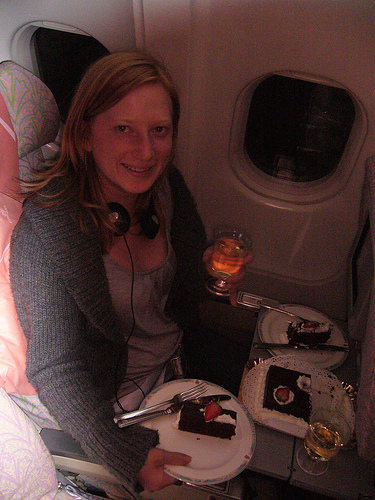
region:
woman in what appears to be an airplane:
[2, 4, 372, 496]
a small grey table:
[238, 296, 360, 491]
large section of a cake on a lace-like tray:
[240, 355, 355, 438]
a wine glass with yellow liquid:
[294, 408, 351, 473]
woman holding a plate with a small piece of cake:
[134, 376, 252, 483]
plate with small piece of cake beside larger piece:
[255, 301, 353, 431]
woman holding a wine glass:
[199, 227, 253, 306]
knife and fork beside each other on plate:
[112, 379, 256, 484]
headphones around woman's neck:
[79, 175, 164, 239]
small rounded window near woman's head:
[76, 49, 367, 195]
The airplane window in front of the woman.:
[246, 61, 352, 197]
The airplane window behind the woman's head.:
[20, 21, 109, 124]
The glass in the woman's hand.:
[214, 227, 242, 307]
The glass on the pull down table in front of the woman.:
[314, 407, 345, 477]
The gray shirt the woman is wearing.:
[71, 189, 173, 373]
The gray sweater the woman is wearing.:
[21, 175, 215, 478]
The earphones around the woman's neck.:
[83, 184, 161, 240]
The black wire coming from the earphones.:
[119, 236, 145, 420]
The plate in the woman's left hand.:
[130, 372, 264, 489]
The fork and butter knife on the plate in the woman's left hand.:
[114, 384, 225, 423]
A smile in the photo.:
[116, 155, 160, 179]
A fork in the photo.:
[115, 379, 210, 419]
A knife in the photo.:
[174, 391, 234, 411]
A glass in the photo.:
[296, 423, 339, 476]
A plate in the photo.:
[199, 443, 255, 483]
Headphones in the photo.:
[106, 203, 168, 238]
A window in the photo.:
[234, 60, 363, 205]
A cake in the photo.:
[176, 404, 241, 439]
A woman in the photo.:
[14, 48, 209, 485]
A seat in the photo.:
[0, 61, 68, 404]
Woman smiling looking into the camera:
[15, 49, 204, 384]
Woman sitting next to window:
[14, 61, 206, 361]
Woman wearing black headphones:
[9, 45, 202, 385]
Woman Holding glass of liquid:
[8, 47, 260, 356]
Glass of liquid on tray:
[291, 403, 355, 480]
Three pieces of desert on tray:
[147, 276, 337, 486]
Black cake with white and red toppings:
[256, 360, 319, 432]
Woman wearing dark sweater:
[14, 71, 216, 382]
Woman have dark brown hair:
[19, 52, 181, 216]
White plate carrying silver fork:
[129, 379, 264, 499]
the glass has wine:
[184, 238, 262, 289]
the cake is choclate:
[163, 392, 248, 437]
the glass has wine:
[299, 411, 358, 468]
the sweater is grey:
[33, 263, 123, 394]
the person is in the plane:
[17, 230, 369, 488]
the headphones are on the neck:
[97, 200, 184, 242]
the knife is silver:
[257, 301, 343, 365]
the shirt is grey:
[116, 272, 193, 396]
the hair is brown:
[81, 65, 175, 101]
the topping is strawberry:
[197, 399, 233, 420]